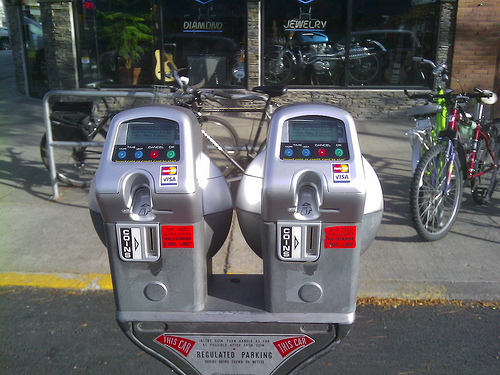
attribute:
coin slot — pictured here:
[306, 226, 317, 254]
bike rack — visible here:
[39, 87, 274, 207]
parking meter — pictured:
[86, 101, 388, 374]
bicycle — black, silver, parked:
[186, 84, 290, 182]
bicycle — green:
[411, 52, 499, 195]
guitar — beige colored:
[154, 46, 180, 84]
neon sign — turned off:
[281, 15, 330, 34]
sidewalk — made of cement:
[2, 47, 500, 301]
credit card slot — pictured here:
[287, 202, 342, 215]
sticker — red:
[159, 223, 195, 252]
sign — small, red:
[322, 224, 357, 250]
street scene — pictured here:
[0, 2, 499, 374]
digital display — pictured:
[286, 120, 338, 144]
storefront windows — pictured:
[72, 0, 440, 87]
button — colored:
[150, 147, 160, 160]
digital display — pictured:
[124, 123, 174, 143]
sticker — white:
[120, 224, 144, 260]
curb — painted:
[2, 273, 499, 311]